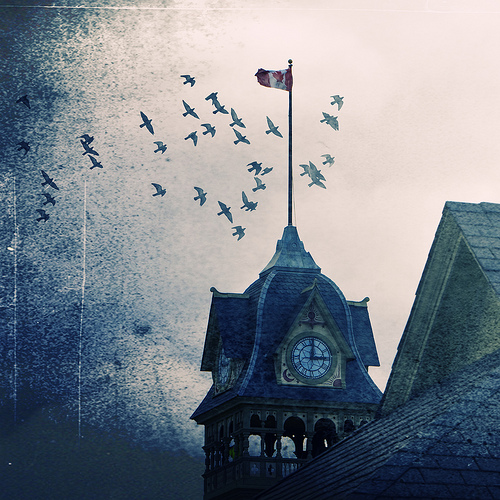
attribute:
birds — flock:
[10, 62, 357, 247]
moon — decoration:
[284, 369, 295, 384]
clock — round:
[284, 330, 339, 386]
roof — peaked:
[374, 196, 499, 423]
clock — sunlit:
[281, 317, 351, 393]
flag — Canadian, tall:
[253, 57, 295, 231]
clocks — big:
[198, 280, 358, 400]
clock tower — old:
[193, 224, 384, 498]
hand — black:
[309, 334, 315, 361]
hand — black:
[308, 353, 330, 360]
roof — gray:
[315, 357, 496, 498]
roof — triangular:
[379, 195, 499, 409]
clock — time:
[290, 335, 333, 380]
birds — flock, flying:
[108, 97, 250, 220]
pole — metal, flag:
[278, 167, 300, 223]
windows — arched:
[187, 392, 364, 463]